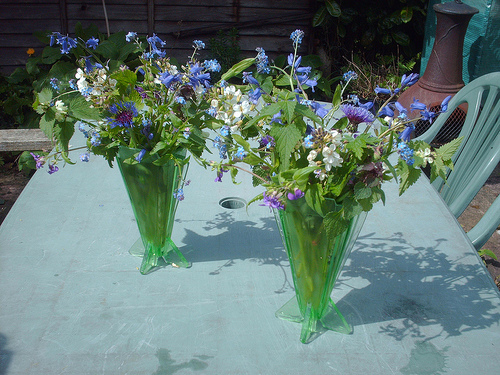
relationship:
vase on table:
[113, 142, 195, 274] [5, 94, 498, 374]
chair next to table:
[408, 70, 500, 249] [5, 94, 498, 374]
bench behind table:
[34, 65, 428, 343] [52, 61, 485, 361]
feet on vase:
[275, 294, 355, 341] [267, 188, 374, 343]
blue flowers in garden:
[32, 29, 460, 217] [0, 30, 147, 127]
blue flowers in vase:
[32, 29, 460, 217] [269, 193, 357, 343]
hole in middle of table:
[219, 196, 248, 210] [5, 94, 498, 374]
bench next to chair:
[0, 99, 500, 374] [443, 91, 495, 207]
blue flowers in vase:
[32, 29, 460, 217] [278, 207, 350, 335]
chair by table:
[458, 54, 498, 244] [5, 94, 498, 374]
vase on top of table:
[276, 195, 370, 343] [24, 233, 122, 322]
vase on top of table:
[115, 155, 192, 275] [24, 233, 122, 322]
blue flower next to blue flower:
[374, 73, 409, 119] [413, 98, 453, 147]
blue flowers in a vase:
[38, 17, 460, 211] [103, 133, 230, 299]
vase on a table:
[275, 195, 358, 345] [5, 94, 498, 374]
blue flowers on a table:
[32, 29, 460, 217] [5, 94, 498, 374]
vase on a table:
[115, 155, 192, 275] [5, 94, 498, 374]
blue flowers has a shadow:
[32, 29, 460, 217] [322, 238, 500, 348]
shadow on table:
[322, 238, 500, 348] [5, 94, 498, 374]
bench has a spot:
[0, 99, 500, 374] [153, 349, 205, 371]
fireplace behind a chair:
[419, 2, 464, 99] [413, 75, 484, 246]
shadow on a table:
[382, 247, 474, 319] [64, 267, 165, 346]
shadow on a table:
[183, 204, 287, 272] [5, 94, 498, 374]